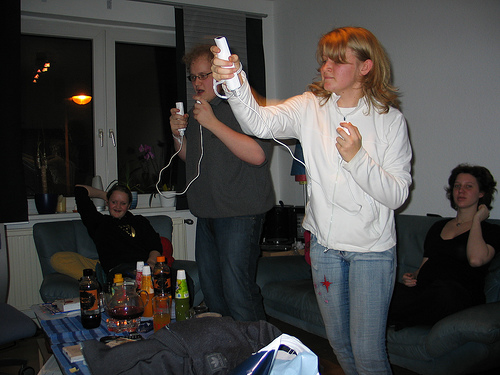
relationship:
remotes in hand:
[208, 39, 264, 108] [312, 110, 387, 167]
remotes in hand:
[163, 79, 215, 146] [312, 110, 387, 167]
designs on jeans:
[311, 270, 336, 305] [312, 240, 406, 371]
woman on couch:
[377, 157, 499, 325] [179, 185, 498, 375]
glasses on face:
[307, 46, 389, 79] [282, 10, 401, 107]